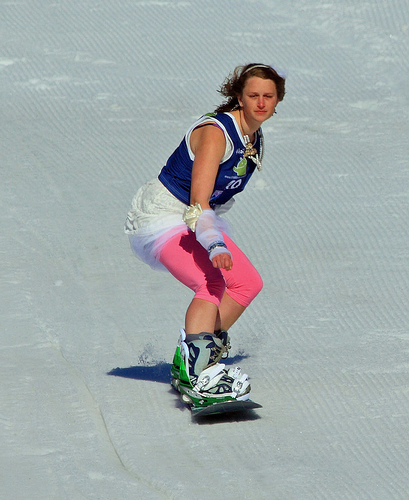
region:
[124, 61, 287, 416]
a woman snowboarding on a snowboard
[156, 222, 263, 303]
the pink leggings of a woman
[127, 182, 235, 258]
the white skirt of a woman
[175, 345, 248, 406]
the white and green bindings of a snowboard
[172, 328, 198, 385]
white and green binding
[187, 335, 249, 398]
grey and blue snowboard boot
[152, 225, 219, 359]
the leg of a woman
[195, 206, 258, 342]
the leg of a woman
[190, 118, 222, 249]
the arm of a woman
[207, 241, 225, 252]
the silver bracelet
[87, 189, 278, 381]
the girl in pink shorts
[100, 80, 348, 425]
the girl in pink shorts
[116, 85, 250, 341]
the girl in pink shorts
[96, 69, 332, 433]
a woman snowboarding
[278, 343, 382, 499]
snowboard tracks in the snow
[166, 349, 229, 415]
green snowboard shoes on a woman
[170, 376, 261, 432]
a white snowboard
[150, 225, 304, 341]
pink tights on a snowboarder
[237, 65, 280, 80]
a white headband on the snowboarder's head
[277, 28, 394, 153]
footprints in the white snow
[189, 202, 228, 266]
white gauze around the woman's arm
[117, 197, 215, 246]
a white gauze skirt on the snowboarder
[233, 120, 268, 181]
a brown and white necklace on the snowboarder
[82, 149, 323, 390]
a girl in pink short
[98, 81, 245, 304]
a girl in pink short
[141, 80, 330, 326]
a girl in pink short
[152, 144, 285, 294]
a girl in pink short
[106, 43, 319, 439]
Woman on snowboard wearing blue and pink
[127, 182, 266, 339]
White skirt and pink pants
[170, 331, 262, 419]
snowboarding boats with green on back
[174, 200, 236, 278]
White stuff on arm with bow at top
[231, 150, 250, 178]
Green character on blue shirt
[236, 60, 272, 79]
White hair band in hair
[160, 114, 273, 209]
Shirt is blue with number 10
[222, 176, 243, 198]
Number 10 in white on blue shirt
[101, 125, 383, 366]
Grid lines on snow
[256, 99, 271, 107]
Nose on woman is red